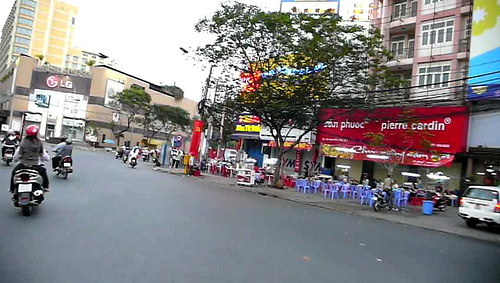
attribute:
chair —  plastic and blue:
[296, 176, 308, 194]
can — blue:
[416, 193, 438, 218]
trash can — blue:
[419, 199, 436, 217]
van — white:
[456, 184, 498, 232]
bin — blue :
[422, 181, 456, 206]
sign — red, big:
[319, 108, 469, 163]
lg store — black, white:
[20, 62, 95, 154]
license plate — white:
[17, 184, 31, 191]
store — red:
[287, 82, 479, 210]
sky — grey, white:
[128, 14, 181, 64]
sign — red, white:
[302, 107, 499, 189]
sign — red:
[187, 117, 204, 158]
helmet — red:
[25, 122, 37, 137]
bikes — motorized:
[39, 105, 101, 230]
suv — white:
[459, 185, 499, 233]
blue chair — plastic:
[388, 188, 410, 208]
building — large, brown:
[16, 37, 206, 150]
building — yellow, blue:
[7, 5, 82, 70]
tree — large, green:
[177, 1, 409, 187]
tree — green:
[254, 50, 314, 185]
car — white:
[455, 185, 498, 222]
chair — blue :
[293, 176, 302, 191]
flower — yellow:
[470, 0, 498, 35]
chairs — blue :
[290, 167, 381, 205]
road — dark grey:
[143, 212, 210, 248]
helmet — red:
[23, 123, 41, 139]